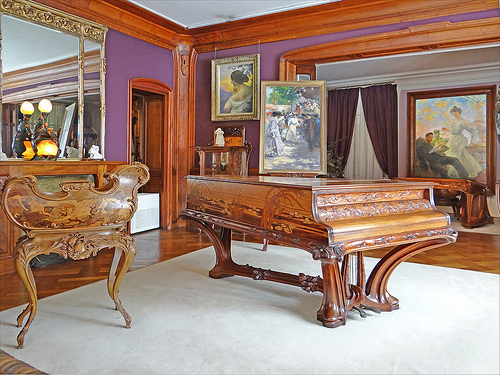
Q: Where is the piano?
A: On the white rug.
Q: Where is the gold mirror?
A: Hanging on the wall.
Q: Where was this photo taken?
A: In a room full of antiques.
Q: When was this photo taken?
A: During the daytime.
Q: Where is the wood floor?
A: Under the white rug.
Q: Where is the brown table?
A: On the left side.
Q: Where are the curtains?
A: On the window in the background.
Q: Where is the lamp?
A: In front of the mirror.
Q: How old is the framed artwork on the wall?
A: Old.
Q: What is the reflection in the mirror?
A: Lamp.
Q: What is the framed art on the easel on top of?
A: Piano.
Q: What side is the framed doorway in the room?
A: Left.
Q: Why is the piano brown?
A: It is wood.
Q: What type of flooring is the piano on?
A: White carpet.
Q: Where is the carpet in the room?
A: Center.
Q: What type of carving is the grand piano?
A: Ornate.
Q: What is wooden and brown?
A: Piano.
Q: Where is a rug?
A: On the floor.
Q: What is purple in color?
A: Walls.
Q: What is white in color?
A: Area rug.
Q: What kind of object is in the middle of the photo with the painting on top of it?
A: Piano.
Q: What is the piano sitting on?
A: Rug.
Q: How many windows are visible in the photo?
A: One.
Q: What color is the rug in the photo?
A: Light grey.